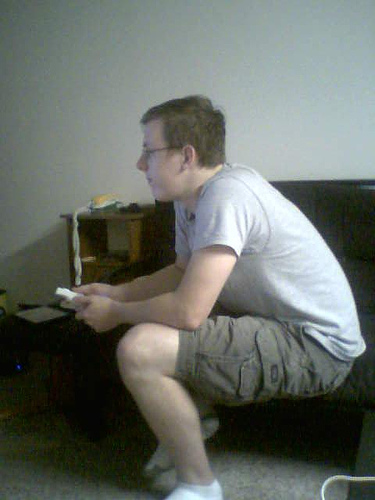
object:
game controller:
[54, 283, 93, 314]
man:
[64, 92, 366, 500]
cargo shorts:
[172, 313, 356, 405]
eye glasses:
[136, 134, 184, 154]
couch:
[83, 177, 375, 495]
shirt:
[172, 164, 367, 360]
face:
[135, 108, 197, 204]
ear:
[182, 141, 195, 166]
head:
[134, 94, 229, 202]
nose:
[135, 155, 150, 173]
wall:
[244, 0, 371, 178]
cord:
[322, 474, 374, 482]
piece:
[344, 465, 373, 476]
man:
[185, 259, 336, 348]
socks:
[178, 479, 222, 500]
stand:
[3, 296, 51, 368]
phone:
[87, 191, 119, 211]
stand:
[65, 203, 160, 245]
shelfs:
[70, 250, 135, 281]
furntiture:
[99, 215, 139, 237]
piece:
[76, 215, 141, 229]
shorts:
[173, 316, 360, 408]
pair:
[218, 357, 278, 392]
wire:
[307, 477, 368, 500]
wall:
[52, 4, 222, 65]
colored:
[39, 116, 80, 126]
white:
[60, 158, 92, 179]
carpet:
[28, 444, 38, 477]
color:
[73, 454, 120, 472]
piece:
[26, 298, 43, 319]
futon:
[335, 186, 367, 228]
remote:
[52, 283, 96, 303]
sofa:
[293, 182, 348, 197]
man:
[176, 150, 189, 182]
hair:
[137, 91, 225, 170]